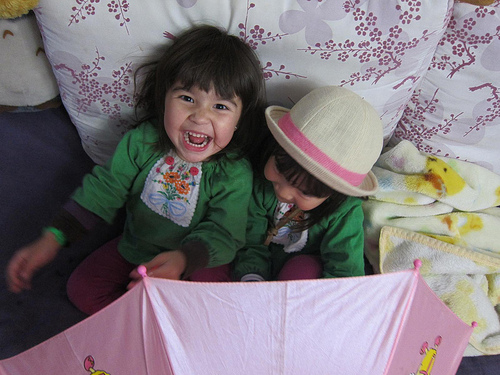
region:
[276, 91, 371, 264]
little girl wearing a white and pink hat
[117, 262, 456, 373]
pink umbrella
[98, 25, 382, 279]
two little girls wearing matching green shirts and pink pants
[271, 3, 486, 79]
white and purple pillows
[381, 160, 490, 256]
white and yellow blanket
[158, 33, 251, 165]
little girl with dark hair smiling at the camera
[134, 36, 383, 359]
two little girls sitting with an umbrella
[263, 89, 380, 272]
girl wearing a green shirt and a white hat with a pink stripe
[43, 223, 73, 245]
green bracelet on the girl's wrist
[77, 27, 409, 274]
two girls wearing matching shirts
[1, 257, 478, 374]
part of a pink umbrella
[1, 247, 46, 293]
a girl's hand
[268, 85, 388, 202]
a beige and pink hat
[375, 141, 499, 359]
a yellow and white blanket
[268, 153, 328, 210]
part of a doll's face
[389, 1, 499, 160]
part of a red and white blanket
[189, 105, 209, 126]
the nose of a girl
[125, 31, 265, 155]
a girl's black short hair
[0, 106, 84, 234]
part of a blue blanket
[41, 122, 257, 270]
a girl's long sleeve shirt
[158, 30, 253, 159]
the toddler is smiling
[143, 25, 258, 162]
the toddler has long hair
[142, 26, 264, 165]
the toddler's hair is dark brown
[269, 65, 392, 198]
the toddler is wearing a hat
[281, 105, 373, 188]
the hat has a pink band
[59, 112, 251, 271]
the toddler is wearing a long sleeve shirt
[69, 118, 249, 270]
the shirt is green in color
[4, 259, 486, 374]
an umbrella is in the front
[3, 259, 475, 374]
the umbrella is pink in color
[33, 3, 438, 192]
a pillow is behind the toddler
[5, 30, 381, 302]
two kids sitting on a bed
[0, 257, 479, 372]
a opened pink umbrella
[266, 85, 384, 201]
a straw hat with a pink bow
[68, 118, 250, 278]
girl wearing a long sleeve green shirt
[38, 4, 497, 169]
white pillows with purple stiched flowers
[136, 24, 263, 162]
a girl with black hair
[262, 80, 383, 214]
a girl wearing a straw hat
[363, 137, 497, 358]
a crumpled white and yellow blanket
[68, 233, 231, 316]
a girl wearing pink pants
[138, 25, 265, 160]
a girl with her head on a pillow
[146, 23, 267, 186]
little girl with dark brown hair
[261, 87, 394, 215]
little girl with tan and pink hat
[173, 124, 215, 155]
little girl is smiling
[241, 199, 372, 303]
little girl is wearing a green shirt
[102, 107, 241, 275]
little girl is wearing a green shirt with flowers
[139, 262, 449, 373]
pink and white umbrella in front of girls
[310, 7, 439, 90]
tree designs on the pillows behind the girls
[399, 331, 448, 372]
yellow and pink design on the umbrella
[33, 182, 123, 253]
black and gray sleeves under the green shirt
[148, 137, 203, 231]
orange and pink flowers in the middle of the green shirt